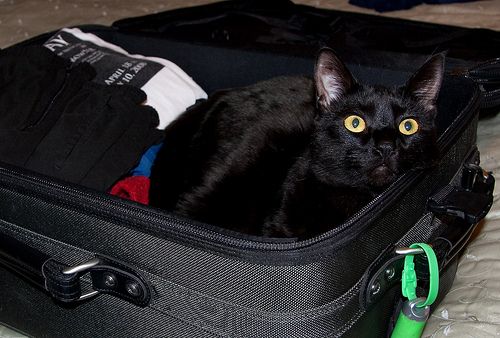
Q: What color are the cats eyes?
A: Yellow and black.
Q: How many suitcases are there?
A: 1.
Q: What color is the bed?
A: White.